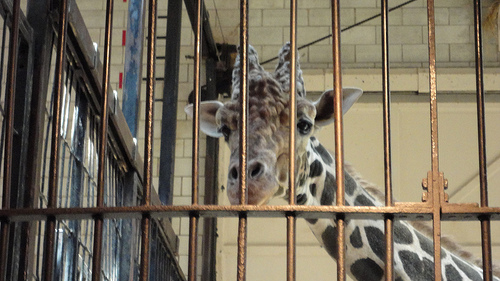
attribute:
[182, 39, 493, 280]
giraffe — yellow, brown, white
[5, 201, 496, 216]
bar — horizontal, metal, rusty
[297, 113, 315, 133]
eye — black